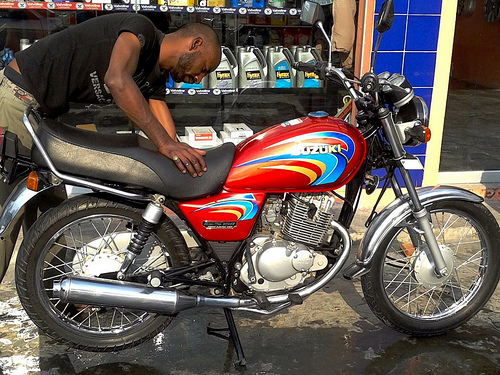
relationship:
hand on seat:
[157, 141, 211, 178] [37, 117, 238, 203]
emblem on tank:
[292, 141, 341, 158] [224, 110, 367, 194]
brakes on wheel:
[367, 168, 396, 225] [344, 186, 499, 338]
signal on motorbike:
[27, 170, 44, 193] [0, 3, 500, 369]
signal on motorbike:
[417, 124, 436, 144] [0, 3, 500, 369]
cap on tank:
[305, 109, 330, 120] [224, 110, 367, 194]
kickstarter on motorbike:
[148, 264, 228, 292] [0, 3, 500, 369]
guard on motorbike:
[180, 192, 266, 242] [0, 3, 500, 369]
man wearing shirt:
[2, 12, 223, 214] [16, 12, 163, 120]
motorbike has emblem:
[0, 3, 500, 369] [288, 141, 342, 158]